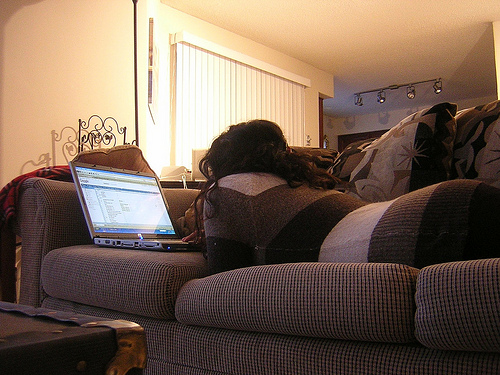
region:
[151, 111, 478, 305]
a woman laying on a couch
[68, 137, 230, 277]
a silver laptop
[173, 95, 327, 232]
a woman with dark hair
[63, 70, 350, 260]
a woman using a laptop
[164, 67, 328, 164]
white vertical blinds covering a doorway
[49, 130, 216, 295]
a laptop on a couch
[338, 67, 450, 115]
track lighting on the cieling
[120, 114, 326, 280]
a woman with her hand on a laptop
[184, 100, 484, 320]
a woman on a couch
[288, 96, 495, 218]
pillows on a couch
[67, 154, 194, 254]
laptop with power turned on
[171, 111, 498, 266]
girl laying on her stomach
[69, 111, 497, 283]
girl on couch, using laptop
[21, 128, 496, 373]
brown and black checkered couch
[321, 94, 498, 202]
brown, black, grey, and tan patterned throw pillows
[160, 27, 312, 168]
vertical blinds on window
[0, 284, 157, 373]
edge of trunk on floor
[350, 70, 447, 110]
can lights hanging from ceiling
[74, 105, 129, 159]
top of kitchen shelving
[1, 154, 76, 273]
red and black blanket on arm of couch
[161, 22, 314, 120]
White vertical blinds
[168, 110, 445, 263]
A woman wearing a striped sweater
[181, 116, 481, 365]
A woman on her stomach on a couch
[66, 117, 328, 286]
A lady looking at a laptop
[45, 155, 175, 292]
A laptop on a couch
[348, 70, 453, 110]
A row of lights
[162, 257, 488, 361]
Brown couch cushions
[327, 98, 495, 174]
Pillows on a couch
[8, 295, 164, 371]
The corner of a trunk coffee table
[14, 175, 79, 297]
The arm of a couch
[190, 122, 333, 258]
this is the woman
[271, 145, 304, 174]
the hair is long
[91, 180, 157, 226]
this is the laptop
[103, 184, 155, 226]
the laptop is on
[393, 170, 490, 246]
this is the butt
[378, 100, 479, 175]
this is the pillow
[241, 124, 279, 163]
the hair is black in color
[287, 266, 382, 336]
the cusions is brown in color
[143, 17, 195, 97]
this is the wall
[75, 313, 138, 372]
this is the table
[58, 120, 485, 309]
a woman laying on a couch using her laptop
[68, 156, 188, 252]
a silver laptop computer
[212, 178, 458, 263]
a brown, black, and white striped sweater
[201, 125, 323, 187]
a woman's wavy black hair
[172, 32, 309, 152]
white window blinds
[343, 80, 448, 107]
silver lights hanging from the ceiling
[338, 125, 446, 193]
decorative couch pillows with a pattern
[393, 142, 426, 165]
gold star on a couch pillow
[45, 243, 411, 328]
fluffy brown couch cushions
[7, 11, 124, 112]
cream-colored wall reflecting a light